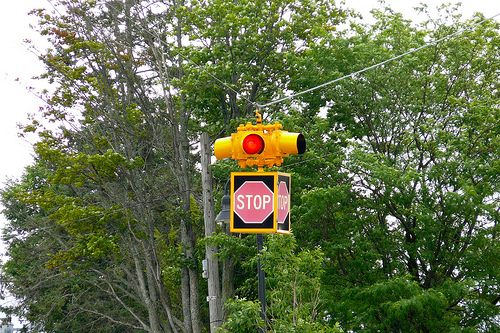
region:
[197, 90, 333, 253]
signal for a four way stop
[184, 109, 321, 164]
a flashing red light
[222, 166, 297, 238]
stop sign surrounded by yellow border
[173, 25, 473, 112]
cable holding up traffic signal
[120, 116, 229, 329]
a group of tree trunks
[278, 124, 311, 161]
a shield for ease of vision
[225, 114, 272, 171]
light that is red at the moment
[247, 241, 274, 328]
a post among the trees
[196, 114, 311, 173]
yellow framework holding the traffic light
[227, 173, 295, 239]
stop signs that are only pink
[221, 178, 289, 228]
stop sign below the light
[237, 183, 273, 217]
white and red sign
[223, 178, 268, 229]
the word "stop"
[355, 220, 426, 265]
green trees behind the sign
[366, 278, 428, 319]
green leaves on the tree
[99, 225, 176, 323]
branches of the trees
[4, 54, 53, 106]
white sky behind the trees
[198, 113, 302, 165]
three lights facing different directions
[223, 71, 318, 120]
rope holding the light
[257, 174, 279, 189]
blackness behind the stop sign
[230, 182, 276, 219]
red and white sign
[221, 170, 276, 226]
red sign with black background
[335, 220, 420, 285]
green tree behind the light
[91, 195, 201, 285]
brown branches on tree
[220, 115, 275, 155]
red light above stop sign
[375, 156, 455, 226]
leaves on the tree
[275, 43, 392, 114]
rope holding the light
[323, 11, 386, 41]
sy behind the trees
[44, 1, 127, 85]
top of the tree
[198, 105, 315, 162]
Bright yellow stop light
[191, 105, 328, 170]
Stoplight with only a red light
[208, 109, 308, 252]
Stop sign below a stop light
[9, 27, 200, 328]
Tall and leafy trees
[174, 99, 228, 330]
Power pole mixed in with the trees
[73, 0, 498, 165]
Power line holding up a light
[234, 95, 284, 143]
Bracket connecting light to wire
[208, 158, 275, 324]
Black metal light post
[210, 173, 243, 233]
Black street light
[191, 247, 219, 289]
Box on the side of a pole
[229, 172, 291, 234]
the hanging stop signs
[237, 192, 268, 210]
the word STOP in white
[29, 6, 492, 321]
the group of big green trees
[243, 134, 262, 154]
the red stop light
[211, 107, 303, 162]
the hanging street lights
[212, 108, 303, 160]
the hanging yellow street lights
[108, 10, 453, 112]
the wire holding the street lights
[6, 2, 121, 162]
the sky behind the trees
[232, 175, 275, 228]
the black area around the stop sign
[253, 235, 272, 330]
the black pole in the trees